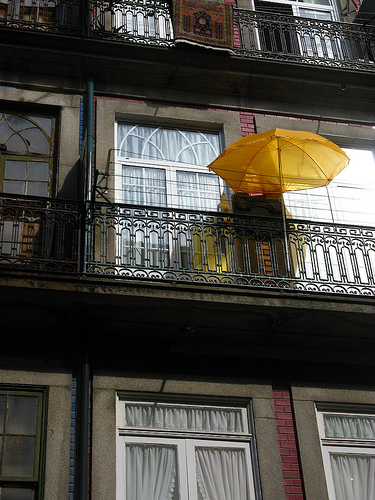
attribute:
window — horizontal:
[188, 438, 261, 499]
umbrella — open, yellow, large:
[206, 127, 352, 197]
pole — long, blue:
[275, 142, 298, 280]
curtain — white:
[129, 438, 252, 499]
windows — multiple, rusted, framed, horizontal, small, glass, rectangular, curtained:
[116, 392, 373, 499]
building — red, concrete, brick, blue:
[0, 1, 375, 500]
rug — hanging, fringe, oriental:
[170, 1, 240, 55]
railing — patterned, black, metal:
[0, 191, 374, 304]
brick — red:
[271, 382, 307, 500]